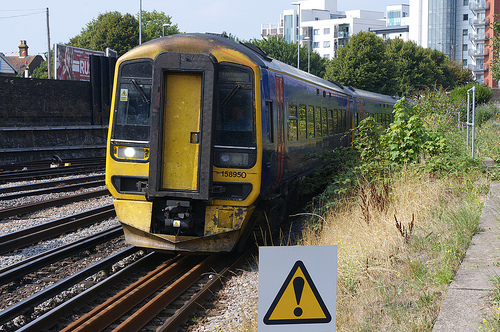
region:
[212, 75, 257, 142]
window of a train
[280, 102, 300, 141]
window of a train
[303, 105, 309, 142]
window of a train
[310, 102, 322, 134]
window of a train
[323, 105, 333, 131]
window of a train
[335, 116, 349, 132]
window of a train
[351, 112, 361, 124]
window of a train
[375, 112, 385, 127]
window of a train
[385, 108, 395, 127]
window of a train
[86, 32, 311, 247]
the front of a train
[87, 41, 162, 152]
the window of a train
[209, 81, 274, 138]
a man on a train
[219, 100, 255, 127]
the head of a man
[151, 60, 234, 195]
a door of a train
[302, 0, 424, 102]
a building near a train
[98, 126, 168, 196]
the headlights on a train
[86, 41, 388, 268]
a train on train tracks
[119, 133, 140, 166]
a lighy on the front of the train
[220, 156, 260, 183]
numbers on the front of the train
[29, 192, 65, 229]
gravel between the tracks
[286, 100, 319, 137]
windows on the train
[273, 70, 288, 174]
doors on the train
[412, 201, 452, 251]
grass growing on the ground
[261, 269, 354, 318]
sign on the ground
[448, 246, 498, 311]
concrete next to the train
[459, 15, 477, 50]
windows on a building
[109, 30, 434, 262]
A train on the tracks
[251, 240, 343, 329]
A cautionary sign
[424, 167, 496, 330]
A cement grey sidewalk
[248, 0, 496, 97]
Building behind tall bushes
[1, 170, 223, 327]
Different sets of train tracks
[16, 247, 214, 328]
Train tracks on gravel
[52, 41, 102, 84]
An advertisement billboard for a movie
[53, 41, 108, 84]
A red and white billboard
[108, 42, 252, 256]
The front of a train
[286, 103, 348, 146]
Windows on a train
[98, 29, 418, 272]
A train in the foreground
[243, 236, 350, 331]
A white sign in the foreground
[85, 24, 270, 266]
End part of the train is yellow in color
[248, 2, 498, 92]
Buildings in the background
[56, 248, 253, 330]
Train track is rusted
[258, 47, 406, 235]
Side of the train is blue in color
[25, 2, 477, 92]
Tall trees in the foreground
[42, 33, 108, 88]
A red poster sign in the background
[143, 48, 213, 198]
Train door is yellow in color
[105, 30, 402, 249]
yellow and blue train cars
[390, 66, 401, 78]
green leaves on the tree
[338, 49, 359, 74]
green leaves on the tree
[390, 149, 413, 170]
green leaves on the tree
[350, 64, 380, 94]
green leaves on the tree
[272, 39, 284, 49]
green leaves on the tree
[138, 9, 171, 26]
green leaves on the tree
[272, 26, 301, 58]
green leaves on the tree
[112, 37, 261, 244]
front of a train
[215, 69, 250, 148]
window of a train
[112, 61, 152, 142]
window of a train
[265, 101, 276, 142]
window of a train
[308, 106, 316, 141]
window of a train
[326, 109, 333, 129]
window of a train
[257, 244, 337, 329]
sign by the tracks